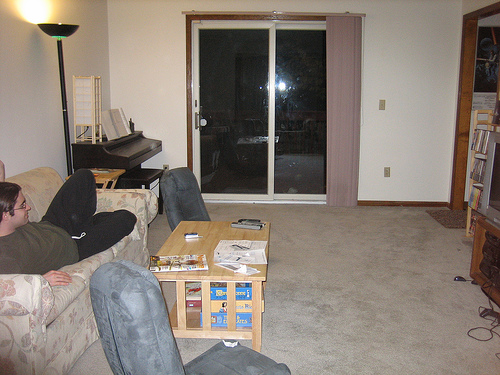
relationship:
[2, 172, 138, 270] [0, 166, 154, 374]
man on top of couch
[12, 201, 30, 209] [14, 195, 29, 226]
glasses on top of face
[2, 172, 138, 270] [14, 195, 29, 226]
man has face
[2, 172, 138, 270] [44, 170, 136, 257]
man wearing pants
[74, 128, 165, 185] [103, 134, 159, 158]
piano has lid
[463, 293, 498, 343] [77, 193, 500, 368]
cords on top of carpet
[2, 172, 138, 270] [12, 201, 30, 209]
man wearing glasses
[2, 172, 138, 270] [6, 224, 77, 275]
man wearing shirt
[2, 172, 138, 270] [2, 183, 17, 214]
man has hair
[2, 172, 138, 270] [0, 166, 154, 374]
man lying on couch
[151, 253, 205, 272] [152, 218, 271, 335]
magazine on coffee table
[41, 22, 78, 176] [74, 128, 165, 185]
lamp next to piano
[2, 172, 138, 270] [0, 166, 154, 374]
man laying on top of couch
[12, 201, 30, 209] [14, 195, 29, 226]
glasses on face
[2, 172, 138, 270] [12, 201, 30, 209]
man has glasses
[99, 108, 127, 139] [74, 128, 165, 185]
sheet music on top of piano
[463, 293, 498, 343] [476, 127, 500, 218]
cords in front of tv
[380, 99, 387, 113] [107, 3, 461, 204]
power outlet against wall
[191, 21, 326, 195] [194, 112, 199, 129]
door has handle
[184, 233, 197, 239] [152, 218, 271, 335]
cell phone on coffee table